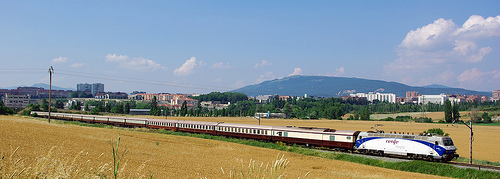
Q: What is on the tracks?
A: A long train.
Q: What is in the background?
A: Buildings and mountains.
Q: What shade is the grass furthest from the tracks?
A: Brown.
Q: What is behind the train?
A: Buildings.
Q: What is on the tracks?
A: A train.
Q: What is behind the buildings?
A: A mountain.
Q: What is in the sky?
A: Clouds.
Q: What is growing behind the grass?
A: Trees.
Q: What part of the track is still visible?
A: The front.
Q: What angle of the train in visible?
A: The side.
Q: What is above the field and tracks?
A: A power line.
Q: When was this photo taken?
A: Daytime.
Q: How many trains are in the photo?
A: One.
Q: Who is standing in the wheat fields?
A: No one.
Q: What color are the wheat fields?
A: Gold.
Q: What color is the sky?
A: Blue.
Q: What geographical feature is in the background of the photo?
A: Mountains.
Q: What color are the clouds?
A: White.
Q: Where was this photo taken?
A: Train track.